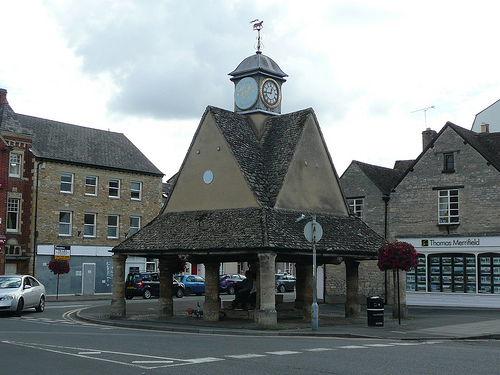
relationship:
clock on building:
[225, 27, 300, 125] [105, 17, 391, 329]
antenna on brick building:
[411, 98, 439, 129] [386, 119, 500, 310]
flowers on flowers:
[375, 240, 420, 271] [375, 240, 420, 271]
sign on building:
[426, 239, 490, 246] [317, 120, 498, 310]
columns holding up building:
[103, 249, 283, 339] [88, 13, 417, 327]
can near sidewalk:
[361, 292, 391, 329] [354, 315, 498, 340]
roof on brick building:
[15, 107, 172, 176] [35, 162, 161, 242]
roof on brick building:
[357, 105, 496, 187] [347, 143, 494, 230]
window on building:
[59, 174, 70, 191] [14, 111, 164, 302]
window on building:
[83, 175, 96, 195] [14, 111, 164, 302]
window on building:
[107, 178, 117, 197] [14, 111, 164, 302]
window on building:
[60, 211, 72, 235] [14, 111, 164, 302]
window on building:
[84, 212, 94, 237] [14, 111, 164, 302]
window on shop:
[403, 252, 499, 292] [387, 117, 499, 310]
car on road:
[125, 269, 187, 301] [0, 293, 499, 373]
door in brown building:
[60, 257, 121, 305] [50, 147, 271, 309]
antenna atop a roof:
[411, 104, 438, 130] [353, 123, 480, 176]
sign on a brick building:
[51, 237, 73, 263] [0, 88, 165, 296]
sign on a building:
[421, 239, 481, 247] [337, 120, 484, 317]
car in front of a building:
[125, 271, 188, 300] [0, 86, 164, 293]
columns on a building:
[111, 252, 409, 329] [88, 13, 417, 327]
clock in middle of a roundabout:
[260, 77, 283, 108] [2, 278, 497, 373]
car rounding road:
[0, 272, 45, 315] [0, 293, 499, 373]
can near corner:
[366, 295, 385, 328] [356, 305, 498, 336]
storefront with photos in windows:
[390, 230, 484, 294] [403, 237, 499, 287]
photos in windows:
[417, 257, 484, 284] [403, 237, 499, 287]